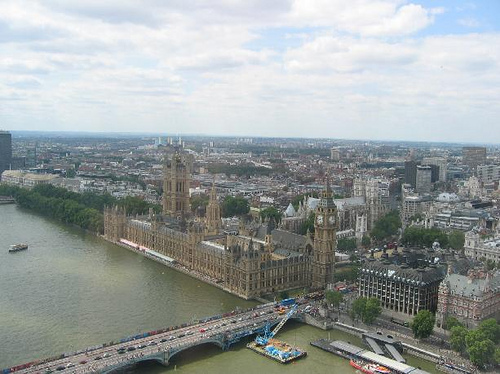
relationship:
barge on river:
[245, 301, 308, 365] [7, 240, 234, 338]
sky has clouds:
[6, 3, 498, 143] [306, 5, 427, 49]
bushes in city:
[29, 191, 107, 231] [68, 114, 497, 324]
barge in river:
[245, 301, 308, 365] [7, 240, 234, 338]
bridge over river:
[64, 319, 316, 366] [7, 240, 234, 338]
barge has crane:
[267, 334, 298, 362] [276, 310, 303, 341]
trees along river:
[442, 317, 499, 362] [7, 240, 234, 338]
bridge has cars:
[64, 319, 316, 366] [200, 313, 277, 326]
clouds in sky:
[306, 5, 427, 49] [6, 3, 498, 143]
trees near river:
[442, 317, 499, 362] [7, 240, 234, 338]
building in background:
[275, 181, 372, 297] [31, 121, 489, 264]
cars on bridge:
[200, 313, 277, 326] [64, 319, 316, 366]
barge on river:
[267, 334, 298, 362] [7, 240, 234, 338]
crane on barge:
[276, 310, 303, 341] [267, 334, 298, 362]